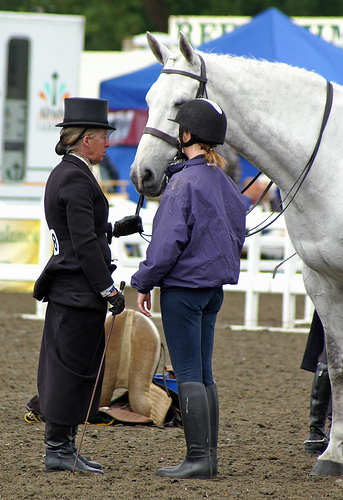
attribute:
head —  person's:
[167, 96, 227, 158]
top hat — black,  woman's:
[57, 102, 112, 132]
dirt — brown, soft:
[0, 277, 340, 497]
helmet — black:
[170, 100, 236, 149]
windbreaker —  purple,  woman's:
[128, 159, 246, 291]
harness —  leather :
[285, 80, 338, 162]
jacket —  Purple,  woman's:
[148, 169, 258, 297]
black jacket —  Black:
[30, 153, 113, 310]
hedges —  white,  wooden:
[26, 244, 324, 424]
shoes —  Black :
[37, 418, 111, 477]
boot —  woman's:
[30, 391, 105, 481]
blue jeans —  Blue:
[159, 282, 224, 381]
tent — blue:
[89, 8, 342, 171]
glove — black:
[104, 289, 128, 315]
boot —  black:
[155, 379, 212, 480]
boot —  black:
[203, 380, 218, 475]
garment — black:
[37, 156, 126, 474]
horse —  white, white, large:
[129, 29, 342, 475]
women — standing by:
[32, 97, 247, 478]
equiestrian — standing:
[157, 103, 245, 315]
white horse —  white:
[131, 28, 341, 477]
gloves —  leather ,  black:
[104, 288, 125, 314]